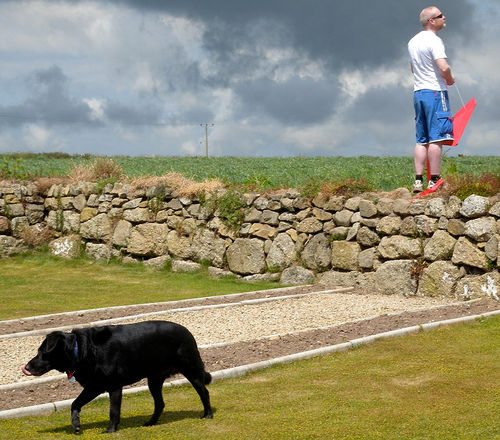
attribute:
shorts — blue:
[412, 88, 453, 145]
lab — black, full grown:
[23, 321, 213, 436]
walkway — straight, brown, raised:
[1, 284, 500, 417]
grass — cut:
[0, 246, 292, 320]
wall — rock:
[2, 178, 499, 299]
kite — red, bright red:
[447, 99, 477, 148]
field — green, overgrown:
[2, 150, 499, 195]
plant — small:
[216, 193, 246, 235]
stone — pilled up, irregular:
[226, 236, 266, 275]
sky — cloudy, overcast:
[1, 2, 499, 157]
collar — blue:
[73, 338, 80, 361]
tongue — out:
[23, 365, 30, 378]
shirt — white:
[408, 28, 450, 91]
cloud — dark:
[231, 73, 346, 129]